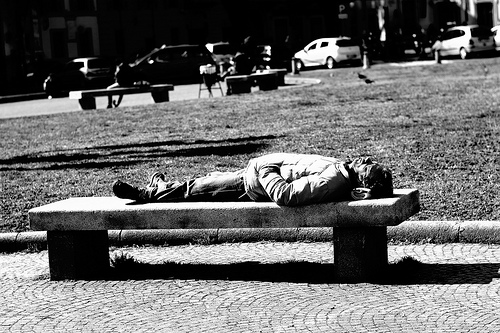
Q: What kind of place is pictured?
A: It is a park.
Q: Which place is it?
A: It is a park.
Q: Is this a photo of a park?
A: Yes, it is showing a park.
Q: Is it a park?
A: Yes, it is a park.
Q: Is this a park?
A: Yes, it is a park.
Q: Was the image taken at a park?
A: Yes, it was taken in a park.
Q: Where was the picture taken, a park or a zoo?
A: It was taken at a park.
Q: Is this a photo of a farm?
A: No, the picture is showing a park.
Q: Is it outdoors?
A: Yes, it is outdoors.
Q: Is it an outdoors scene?
A: Yes, it is outdoors.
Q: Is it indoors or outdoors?
A: It is outdoors.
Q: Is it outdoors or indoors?
A: It is outdoors.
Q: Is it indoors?
A: No, it is outdoors.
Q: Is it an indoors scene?
A: No, it is outdoors.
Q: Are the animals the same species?
A: Yes, all the animals are birds.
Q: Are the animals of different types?
A: No, all the animals are birds.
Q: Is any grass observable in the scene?
A: Yes, there is grass.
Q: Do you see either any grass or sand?
A: Yes, there is grass.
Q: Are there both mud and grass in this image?
A: No, there is grass but no mud.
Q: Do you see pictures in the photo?
A: No, there are no pictures.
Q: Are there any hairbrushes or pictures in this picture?
A: No, there are no pictures or hairbrushes.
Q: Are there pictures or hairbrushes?
A: No, there are no pictures or hairbrushes.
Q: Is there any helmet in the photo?
A: No, there are no helmets.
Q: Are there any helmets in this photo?
A: No, there are no helmets.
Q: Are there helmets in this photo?
A: No, there are no helmets.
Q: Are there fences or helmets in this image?
A: No, there are no helmets or fences.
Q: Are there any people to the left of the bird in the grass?
A: Yes, there is a person to the left of the bird.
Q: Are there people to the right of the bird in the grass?
A: No, the person is to the left of the bird.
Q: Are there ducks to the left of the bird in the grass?
A: No, there is a person to the left of the bird.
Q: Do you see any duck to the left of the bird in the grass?
A: No, there is a person to the left of the bird.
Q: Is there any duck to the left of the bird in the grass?
A: No, there is a person to the left of the bird.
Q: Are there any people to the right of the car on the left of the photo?
A: Yes, there is a person to the right of the car.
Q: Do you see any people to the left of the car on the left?
A: No, the person is to the right of the car.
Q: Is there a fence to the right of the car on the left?
A: No, there is a person to the right of the car.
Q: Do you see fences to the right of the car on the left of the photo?
A: No, there is a person to the right of the car.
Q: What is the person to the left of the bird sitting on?
A: The person is sitting on the bench.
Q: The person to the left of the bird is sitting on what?
A: The person is sitting on the bench.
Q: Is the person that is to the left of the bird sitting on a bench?
A: Yes, the person is sitting on a bench.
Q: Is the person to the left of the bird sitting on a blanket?
A: No, the person is sitting on a bench.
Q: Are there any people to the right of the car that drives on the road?
A: Yes, there is a person to the right of the car.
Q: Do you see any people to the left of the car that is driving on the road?
A: No, the person is to the right of the car.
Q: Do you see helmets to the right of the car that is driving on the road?
A: No, there is a person to the right of the car.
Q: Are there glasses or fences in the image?
A: No, there are no fences or glasses.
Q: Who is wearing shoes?
A: The man is wearing shoes.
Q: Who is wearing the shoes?
A: The man is wearing shoes.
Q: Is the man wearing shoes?
A: Yes, the man is wearing shoes.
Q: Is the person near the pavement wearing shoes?
A: Yes, the man is wearing shoes.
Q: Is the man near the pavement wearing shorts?
A: No, the man is wearing shoes.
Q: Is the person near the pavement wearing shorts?
A: No, the man is wearing shoes.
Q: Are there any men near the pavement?
A: Yes, there is a man near the pavement.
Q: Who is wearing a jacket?
A: The man is wearing a jacket.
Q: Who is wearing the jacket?
A: The man is wearing a jacket.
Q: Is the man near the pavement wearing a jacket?
A: Yes, the man is wearing a jacket.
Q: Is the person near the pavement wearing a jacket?
A: Yes, the man is wearing a jacket.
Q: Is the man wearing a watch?
A: No, the man is wearing a jacket.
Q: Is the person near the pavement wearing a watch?
A: No, the man is wearing a jacket.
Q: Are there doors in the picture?
A: Yes, there is a door.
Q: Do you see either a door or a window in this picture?
A: Yes, there is a door.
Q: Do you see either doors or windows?
A: Yes, there is a door.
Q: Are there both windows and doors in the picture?
A: No, there is a door but no windows.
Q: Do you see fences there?
A: No, there are no fences.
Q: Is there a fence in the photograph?
A: No, there are no fences.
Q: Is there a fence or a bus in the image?
A: No, there are no fences or buses.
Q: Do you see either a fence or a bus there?
A: No, there are no fences or buses.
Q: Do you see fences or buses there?
A: No, there are no fences or buses.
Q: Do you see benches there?
A: Yes, there is a bench.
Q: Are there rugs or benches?
A: Yes, there is a bench.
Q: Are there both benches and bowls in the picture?
A: No, there is a bench but no bowls.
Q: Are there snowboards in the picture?
A: No, there are no snowboards.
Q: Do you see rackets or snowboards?
A: No, there are no snowboards or rackets.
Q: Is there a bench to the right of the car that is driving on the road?
A: Yes, there is a bench to the right of the car.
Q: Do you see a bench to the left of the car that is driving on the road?
A: No, the bench is to the right of the car.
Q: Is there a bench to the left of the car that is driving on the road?
A: No, the bench is to the right of the car.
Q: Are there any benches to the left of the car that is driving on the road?
A: No, the bench is to the right of the car.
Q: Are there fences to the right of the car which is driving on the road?
A: No, there is a bench to the right of the car.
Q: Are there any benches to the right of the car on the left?
A: Yes, there is a bench to the right of the car.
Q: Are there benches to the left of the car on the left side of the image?
A: No, the bench is to the right of the car.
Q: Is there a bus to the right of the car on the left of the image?
A: No, there is a bench to the right of the car.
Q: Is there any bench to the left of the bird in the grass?
A: Yes, there is a bench to the left of the bird.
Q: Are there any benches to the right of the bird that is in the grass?
A: No, the bench is to the left of the bird.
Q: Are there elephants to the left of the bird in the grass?
A: No, there is a bench to the left of the bird.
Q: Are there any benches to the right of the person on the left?
A: Yes, there is a bench to the right of the person.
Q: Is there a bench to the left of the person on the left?
A: No, the bench is to the right of the person.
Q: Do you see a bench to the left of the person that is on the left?
A: No, the bench is to the right of the person.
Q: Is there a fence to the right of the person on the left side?
A: No, there is a bench to the right of the person.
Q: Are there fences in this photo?
A: No, there are no fences.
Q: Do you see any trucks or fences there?
A: No, there are no fences or trucks.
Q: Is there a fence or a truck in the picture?
A: No, there are no fences or trucks.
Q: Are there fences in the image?
A: No, there are no fences.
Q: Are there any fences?
A: No, there are no fences.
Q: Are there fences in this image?
A: No, there are no fences.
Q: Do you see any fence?
A: No, there are no fences.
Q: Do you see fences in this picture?
A: No, there are no fences.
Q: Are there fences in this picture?
A: No, there are no fences.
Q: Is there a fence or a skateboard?
A: No, there are no fences or skateboards.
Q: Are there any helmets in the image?
A: No, there are no helmets.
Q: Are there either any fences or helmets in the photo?
A: No, there are no helmets or fences.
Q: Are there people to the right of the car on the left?
A: Yes, there is a person to the right of the car.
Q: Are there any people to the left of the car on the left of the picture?
A: No, the person is to the right of the car.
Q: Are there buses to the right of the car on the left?
A: No, there is a person to the right of the car.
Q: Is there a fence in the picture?
A: No, there are no fences.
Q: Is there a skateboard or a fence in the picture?
A: No, there are no fences or skateboards.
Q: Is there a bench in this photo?
A: Yes, there is a bench.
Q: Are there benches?
A: Yes, there is a bench.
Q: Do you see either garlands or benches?
A: Yes, there is a bench.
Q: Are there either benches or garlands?
A: Yes, there is a bench.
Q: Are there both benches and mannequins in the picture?
A: No, there is a bench but no mannequins.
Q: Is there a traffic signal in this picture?
A: No, there are no traffic lights.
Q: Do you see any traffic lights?
A: No, there are no traffic lights.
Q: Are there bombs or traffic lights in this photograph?
A: No, there are no traffic lights or bombs.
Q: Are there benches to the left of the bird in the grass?
A: Yes, there is a bench to the left of the bird.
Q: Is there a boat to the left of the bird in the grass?
A: No, there is a bench to the left of the bird.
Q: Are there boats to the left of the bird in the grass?
A: No, there is a bench to the left of the bird.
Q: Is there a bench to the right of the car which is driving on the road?
A: Yes, there is a bench to the right of the car.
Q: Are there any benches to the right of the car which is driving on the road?
A: Yes, there is a bench to the right of the car.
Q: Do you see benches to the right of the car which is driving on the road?
A: Yes, there is a bench to the right of the car.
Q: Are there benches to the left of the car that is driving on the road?
A: No, the bench is to the right of the car.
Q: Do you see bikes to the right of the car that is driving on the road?
A: No, there is a bench to the right of the car.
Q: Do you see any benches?
A: Yes, there is a bench.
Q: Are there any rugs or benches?
A: Yes, there is a bench.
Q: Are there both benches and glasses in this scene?
A: No, there is a bench but no glasses.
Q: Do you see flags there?
A: No, there are no flags.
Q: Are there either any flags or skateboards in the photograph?
A: No, there are no flags or skateboards.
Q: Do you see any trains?
A: No, there are no trains.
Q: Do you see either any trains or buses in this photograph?
A: No, there are no trains or buses.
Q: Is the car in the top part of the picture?
A: Yes, the car is in the top of the image.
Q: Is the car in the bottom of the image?
A: No, the car is in the top of the image.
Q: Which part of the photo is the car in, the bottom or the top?
A: The car is in the top of the image.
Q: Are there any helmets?
A: No, there are no helmets.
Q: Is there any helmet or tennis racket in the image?
A: No, there are no helmets or rackets.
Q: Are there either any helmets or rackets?
A: No, there are no helmets or rackets.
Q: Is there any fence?
A: No, there are no fences.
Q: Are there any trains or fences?
A: No, there are no fences or trains.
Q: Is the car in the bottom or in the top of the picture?
A: The car is in the top of the image.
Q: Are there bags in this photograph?
A: No, there are no bags.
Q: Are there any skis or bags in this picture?
A: No, there are no bags or skis.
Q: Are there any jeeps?
A: No, there are no jeeps.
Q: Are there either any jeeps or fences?
A: No, there are no jeeps or fences.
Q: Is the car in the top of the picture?
A: Yes, the car is in the top of the image.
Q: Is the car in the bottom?
A: No, the car is in the top of the image.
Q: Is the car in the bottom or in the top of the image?
A: The car is in the top of the image.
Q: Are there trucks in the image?
A: No, there are no trucks.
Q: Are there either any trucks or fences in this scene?
A: No, there are no trucks or fences.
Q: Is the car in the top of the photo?
A: Yes, the car is in the top of the image.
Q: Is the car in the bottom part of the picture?
A: No, the car is in the top of the image.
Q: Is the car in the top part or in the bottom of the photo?
A: The car is in the top of the image.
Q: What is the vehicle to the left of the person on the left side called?
A: The vehicle is a car.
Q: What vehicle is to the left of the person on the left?
A: The vehicle is a car.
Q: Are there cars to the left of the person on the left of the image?
A: Yes, there is a car to the left of the person.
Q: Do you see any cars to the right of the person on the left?
A: No, the car is to the left of the person.